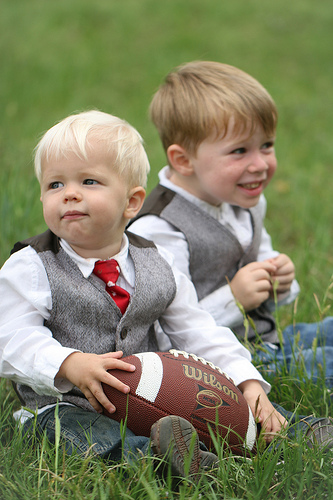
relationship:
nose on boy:
[247, 151, 266, 173] [125, 59, 299, 324]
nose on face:
[247, 151, 266, 173] [221, 125, 276, 207]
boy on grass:
[0, 107, 333, 487] [266, 447, 312, 482]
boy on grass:
[24, 104, 174, 380] [266, 447, 312, 482]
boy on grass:
[124, 59, 332, 384] [266, 447, 312, 482]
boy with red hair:
[154, 70, 300, 313] [150, 46, 290, 156]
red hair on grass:
[150, 46, 290, 156] [259, 371, 331, 472]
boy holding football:
[0, 107, 333, 487] [94, 339, 278, 464]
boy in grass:
[0, 107, 333, 487] [0, 0, 332, 499]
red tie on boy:
[92, 259, 130, 313] [0, 107, 333, 487]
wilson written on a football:
[181, 361, 240, 404] [94, 350, 260, 458]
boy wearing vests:
[0, 107, 333, 487] [18, 187, 265, 408]